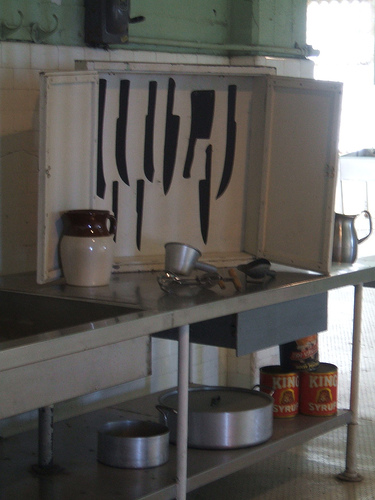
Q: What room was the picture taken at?
A: It was taken at the kitchen.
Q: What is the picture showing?
A: It is showing a kitchen.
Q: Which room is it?
A: It is a kitchen.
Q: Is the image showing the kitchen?
A: Yes, it is showing the kitchen.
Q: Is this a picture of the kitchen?
A: Yes, it is showing the kitchen.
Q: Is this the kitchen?
A: Yes, it is the kitchen.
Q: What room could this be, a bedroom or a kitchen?
A: It is a kitchen.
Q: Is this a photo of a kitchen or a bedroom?
A: It is showing a kitchen.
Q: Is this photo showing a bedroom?
A: No, the picture is showing a kitchen.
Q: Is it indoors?
A: Yes, it is indoors.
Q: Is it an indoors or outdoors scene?
A: It is indoors.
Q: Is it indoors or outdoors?
A: It is indoors.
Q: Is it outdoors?
A: No, it is indoors.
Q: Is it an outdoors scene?
A: No, it is indoors.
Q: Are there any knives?
A: Yes, there is a knife.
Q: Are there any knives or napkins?
A: Yes, there is a knife.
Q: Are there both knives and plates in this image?
A: No, there is a knife but no plates.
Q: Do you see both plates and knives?
A: No, there is a knife but no plates.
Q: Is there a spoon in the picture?
A: No, there are no spoons.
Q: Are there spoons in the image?
A: No, there are no spoons.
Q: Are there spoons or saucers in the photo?
A: No, there are no spoons or saucers.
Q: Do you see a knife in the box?
A: Yes, there is a knife in the box.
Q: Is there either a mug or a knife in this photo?
A: Yes, there is a knife.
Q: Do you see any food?
A: No, there is no food.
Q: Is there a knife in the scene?
A: Yes, there is a knife.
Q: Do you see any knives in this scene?
A: Yes, there is a knife.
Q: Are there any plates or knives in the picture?
A: Yes, there is a knife.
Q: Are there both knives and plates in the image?
A: No, there is a knife but no plates.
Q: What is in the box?
A: The knife is in the box.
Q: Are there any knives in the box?
A: Yes, there is a knife in the box.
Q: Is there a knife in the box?
A: Yes, there is a knife in the box.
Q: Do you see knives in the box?
A: Yes, there is a knife in the box.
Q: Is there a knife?
A: Yes, there is a knife.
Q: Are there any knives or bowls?
A: Yes, there is a knife.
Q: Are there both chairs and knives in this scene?
A: No, there is a knife but no chairs.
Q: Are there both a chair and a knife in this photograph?
A: No, there is a knife but no chairs.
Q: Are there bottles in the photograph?
A: No, there are no bottles.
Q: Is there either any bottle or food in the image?
A: No, there are no bottles or food.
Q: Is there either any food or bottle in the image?
A: No, there are no bottles or food.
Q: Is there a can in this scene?
A: Yes, there is a can.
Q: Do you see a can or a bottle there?
A: Yes, there is a can.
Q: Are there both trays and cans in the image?
A: No, there is a can but no trays.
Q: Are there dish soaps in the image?
A: No, there are no dish soaps.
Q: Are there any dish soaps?
A: No, there are no dish soaps.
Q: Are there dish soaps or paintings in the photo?
A: No, there are no dish soaps or paintings.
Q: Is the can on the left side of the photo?
A: No, the can is on the right of the image.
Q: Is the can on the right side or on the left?
A: The can is on the right of the image.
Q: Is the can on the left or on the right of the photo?
A: The can is on the right of the image.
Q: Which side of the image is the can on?
A: The can is on the right of the image.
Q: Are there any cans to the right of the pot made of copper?
A: Yes, there is a can to the right of the pot.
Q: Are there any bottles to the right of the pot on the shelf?
A: No, there is a can to the right of the pot.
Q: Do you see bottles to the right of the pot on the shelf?
A: No, there is a can to the right of the pot.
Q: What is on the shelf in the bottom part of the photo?
A: The can is on the shelf.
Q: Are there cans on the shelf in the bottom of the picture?
A: Yes, there is a can on the shelf.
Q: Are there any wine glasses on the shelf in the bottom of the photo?
A: No, there is a can on the shelf.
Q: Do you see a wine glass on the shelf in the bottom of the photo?
A: No, there is a can on the shelf.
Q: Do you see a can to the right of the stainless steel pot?
A: Yes, there is a can to the right of the pot.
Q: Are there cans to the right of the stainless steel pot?
A: Yes, there is a can to the right of the pot.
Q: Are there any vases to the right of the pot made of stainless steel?
A: No, there is a can to the right of the pot.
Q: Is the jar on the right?
A: No, the jar is on the left of the image.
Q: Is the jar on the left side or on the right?
A: The jar is on the left of the image.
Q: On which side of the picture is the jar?
A: The jar is on the left of the image.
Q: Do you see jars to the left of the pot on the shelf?
A: Yes, there is a jar to the left of the pot.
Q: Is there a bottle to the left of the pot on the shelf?
A: No, there is a jar to the left of the pot.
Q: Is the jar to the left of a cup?
A: No, the jar is to the left of the pot.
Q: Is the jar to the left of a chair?
A: No, the jar is to the left of a knife.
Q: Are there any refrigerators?
A: No, there are no refrigerators.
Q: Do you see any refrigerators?
A: No, there are no refrigerators.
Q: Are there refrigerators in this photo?
A: No, there are no refrigerators.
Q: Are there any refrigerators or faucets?
A: No, there are no refrigerators or faucets.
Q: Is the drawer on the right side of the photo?
A: Yes, the drawer is on the right of the image.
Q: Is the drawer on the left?
A: No, the drawer is on the right of the image.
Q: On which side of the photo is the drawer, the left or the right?
A: The drawer is on the right of the image.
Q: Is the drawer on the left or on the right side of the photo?
A: The drawer is on the right of the image.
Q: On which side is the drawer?
A: The drawer is on the right of the image.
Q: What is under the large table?
A: The drawer is under the table.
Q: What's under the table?
A: The drawer is under the table.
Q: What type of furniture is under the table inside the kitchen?
A: The piece of furniture is a drawer.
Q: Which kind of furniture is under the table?
A: The piece of furniture is a drawer.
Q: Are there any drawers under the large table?
A: Yes, there is a drawer under the table.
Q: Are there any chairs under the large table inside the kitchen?
A: No, there is a drawer under the table.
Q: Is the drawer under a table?
A: Yes, the drawer is under a table.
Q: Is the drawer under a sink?
A: No, the drawer is under a table.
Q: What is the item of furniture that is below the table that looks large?
A: The piece of furniture is a drawer.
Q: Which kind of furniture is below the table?
A: The piece of furniture is a drawer.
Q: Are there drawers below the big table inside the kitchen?
A: Yes, there is a drawer below the table.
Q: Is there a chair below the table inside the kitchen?
A: No, there is a drawer below the table.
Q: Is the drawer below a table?
A: Yes, the drawer is below a table.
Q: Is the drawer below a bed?
A: No, the drawer is below a table.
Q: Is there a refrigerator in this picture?
A: No, there are no refrigerators.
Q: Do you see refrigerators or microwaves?
A: No, there are no refrigerators or microwaves.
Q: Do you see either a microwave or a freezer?
A: No, there are no refrigerators or microwaves.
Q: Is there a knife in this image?
A: Yes, there is a knife.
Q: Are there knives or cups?
A: Yes, there is a knife.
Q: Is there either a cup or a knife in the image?
A: Yes, there is a knife.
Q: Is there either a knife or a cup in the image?
A: Yes, there is a knife.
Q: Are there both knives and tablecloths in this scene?
A: No, there is a knife but no tablecloths.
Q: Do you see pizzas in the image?
A: No, there are no pizzas.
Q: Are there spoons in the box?
A: No, there is a knife in the box.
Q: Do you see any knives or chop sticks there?
A: Yes, there is a knife.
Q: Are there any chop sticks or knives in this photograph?
A: Yes, there is a knife.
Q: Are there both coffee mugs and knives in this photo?
A: No, there is a knife but no coffee mugs.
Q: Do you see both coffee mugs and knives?
A: No, there is a knife but no coffee mugs.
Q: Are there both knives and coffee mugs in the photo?
A: No, there is a knife but no coffee mugs.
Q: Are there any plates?
A: No, there are no plates.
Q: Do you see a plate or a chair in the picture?
A: No, there are no plates or chairs.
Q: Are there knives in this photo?
A: Yes, there is a knife.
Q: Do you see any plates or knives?
A: Yes, there is a knife.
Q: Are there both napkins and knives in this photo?
A: No, there is a knife but no napkins.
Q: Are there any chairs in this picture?
A: No, there are no chairs.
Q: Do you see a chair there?
A: No, there are no chairs.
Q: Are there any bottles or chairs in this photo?
A: No, there are no chairs or bottles.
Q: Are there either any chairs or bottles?
A: No, there are no chairs or bottles.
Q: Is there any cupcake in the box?
A: No, there is a knife in the box.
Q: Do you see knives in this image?
A: Yes, there is a knife.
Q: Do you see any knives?
A: Yes, there is a knife.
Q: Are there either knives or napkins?
A: Yes, there is a knife.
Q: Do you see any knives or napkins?
A: Yes, there is a knife.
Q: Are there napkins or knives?
A: Yes, there is a knife.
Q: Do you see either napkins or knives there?
A: Yes, there is a knife.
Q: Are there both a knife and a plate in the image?
A: No, there is a knife but no plates.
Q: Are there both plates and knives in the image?
A: No, there is a knife but no plates.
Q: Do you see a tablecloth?
A: No, there are no tablecloths.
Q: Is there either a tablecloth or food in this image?
A: No, there are no tablecloths or food.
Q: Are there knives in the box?
A: Yes, there is a knife in the box.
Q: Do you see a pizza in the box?
A: No, there is a knife in the box.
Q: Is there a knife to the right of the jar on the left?
A: Yes, there is a knife to the right of the jar.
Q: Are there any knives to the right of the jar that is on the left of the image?
A: Yes, there is a knife to the right of the jar.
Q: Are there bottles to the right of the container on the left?
A: No, there is a knife to the right of the jar.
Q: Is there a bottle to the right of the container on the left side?
A: No, there is a knife to the right of the jar.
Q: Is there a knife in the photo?
A: Yes, there is a knife.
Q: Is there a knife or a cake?
A: Yes, there is a knife.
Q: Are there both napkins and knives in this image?
A: No, there is a knife but no napkins.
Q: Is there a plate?
A: No, there are no plates.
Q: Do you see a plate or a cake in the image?
A: No, there are no plates or cakes.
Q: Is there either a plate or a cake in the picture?
A: No, there are no plates or cakes.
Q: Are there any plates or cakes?
A: No, there are no plates or cakes.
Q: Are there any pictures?
A: No, there are no pictures.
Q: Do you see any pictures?
A: No, there are no pictures.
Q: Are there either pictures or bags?
A: No, there are no pictures or bags.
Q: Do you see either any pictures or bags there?
A: No, there are no pictures or bags.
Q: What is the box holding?
A: The box is holding the knives.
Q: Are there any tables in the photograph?
A: Yes, there is a table.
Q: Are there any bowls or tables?
A: Yes, there is a table.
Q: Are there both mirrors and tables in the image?
A: No, there is a table but no mirrors.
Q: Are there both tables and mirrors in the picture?
A: No, there is a table but no mirrors.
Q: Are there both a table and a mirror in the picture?
A: No, there is a table but no mirrors.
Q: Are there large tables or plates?
A: Yes, there is a large table.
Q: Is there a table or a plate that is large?
A: Yes, the table is large.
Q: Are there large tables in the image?
A: Yes, there is a large table.